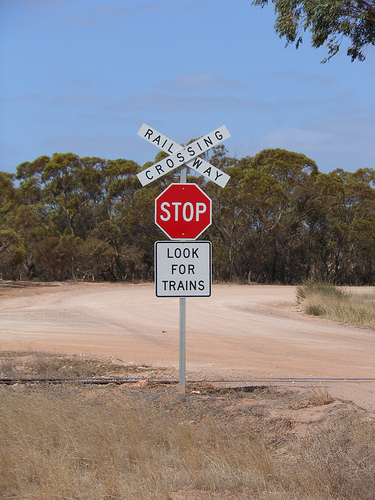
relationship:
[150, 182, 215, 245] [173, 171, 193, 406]
stop sign on post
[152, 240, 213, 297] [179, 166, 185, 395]
sign on pole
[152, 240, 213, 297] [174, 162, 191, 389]
sign on pole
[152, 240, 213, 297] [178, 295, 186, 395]
sign on pole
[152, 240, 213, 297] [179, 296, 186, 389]
sign on pole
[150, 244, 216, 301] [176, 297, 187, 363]
sign on pole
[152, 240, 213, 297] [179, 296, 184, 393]
sign on pole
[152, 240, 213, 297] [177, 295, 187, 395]
sign on pole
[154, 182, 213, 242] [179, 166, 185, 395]
stop sign on pole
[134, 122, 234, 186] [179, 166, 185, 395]
sign on pole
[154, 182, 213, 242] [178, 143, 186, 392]
stop sign on pole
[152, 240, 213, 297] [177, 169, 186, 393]
sign on pole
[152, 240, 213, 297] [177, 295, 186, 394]
sign on pole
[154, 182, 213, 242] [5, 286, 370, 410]
stop sign on road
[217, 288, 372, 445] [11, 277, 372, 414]
line on road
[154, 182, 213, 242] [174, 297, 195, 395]
stop sign on pole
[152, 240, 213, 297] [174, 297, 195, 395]
sign on pole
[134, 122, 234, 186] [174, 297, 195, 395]
sign on pole